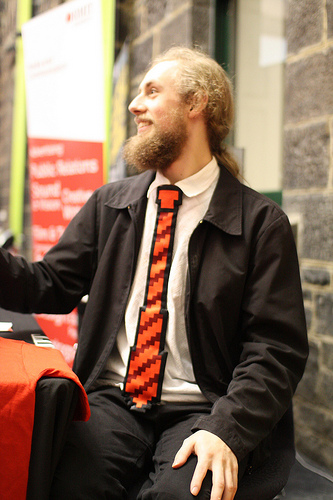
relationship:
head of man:
[119, 48, 244, 171] [11, 45, 313, 496]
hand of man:
[168, 422, 245, 498] [11, 45, 313, 496]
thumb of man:
[170, 442, 189, 475] [11, 45, 313, 496]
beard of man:
[122, 120, 191, 169] [11, 45, 313, 496]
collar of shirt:
[176, 151, 225, 196] [99, 172, 208, 407]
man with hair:
[11, 45, 313, 496] [184, 46, 265, 161]